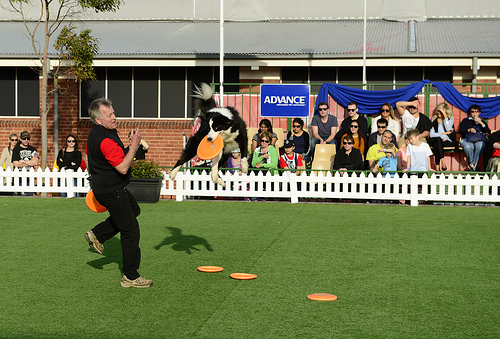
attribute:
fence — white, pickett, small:
[168, 172, 497, 205]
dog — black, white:
[185, 87, 250, 165]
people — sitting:
[258, 96, 499, 183]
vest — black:
[83, 128, 119, 190]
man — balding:
[81, 85, 146, 208]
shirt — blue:
[391, 158, 400, 164]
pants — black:
[101, 199, 155, 282]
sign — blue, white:
[265, 87, 310, 110]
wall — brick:
[57, 90, 77, 118]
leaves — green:
[62, 34, 91, 66]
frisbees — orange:
[194, 256, 265, 282]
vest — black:
[98, 167, 117, 191]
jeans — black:
[96, 192, 145, 278]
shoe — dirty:
[84, 223, 97, 250]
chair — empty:
[311, 143, 340, 170]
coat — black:
[215, 116, 241, 125]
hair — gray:
[91, 100, 97, 117]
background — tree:
[25, 17, 59, 131]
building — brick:
[44, 55, 83, 121]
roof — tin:
[108, 8, 358, 56]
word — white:
[262, 94, 270, 105]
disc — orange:
[304, 277, 345, 311]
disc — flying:
[190, 148, 216, 159]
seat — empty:
[309, 159, 343, 183]